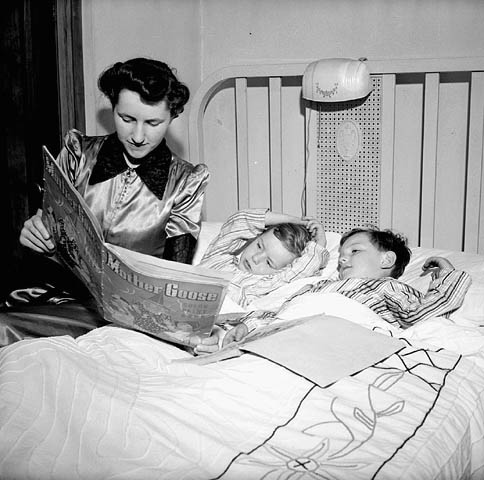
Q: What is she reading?
A: Nursery rhymes.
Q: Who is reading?
A: The mother or sister.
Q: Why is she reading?
A: Calms down the kids.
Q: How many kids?
A: 2.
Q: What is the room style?
A: 1940's.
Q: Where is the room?
A: Bedroom.